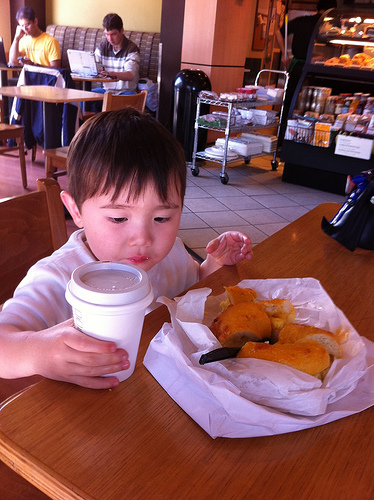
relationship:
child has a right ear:
[3, 98, 254, 390] [54, 188, 84, 228]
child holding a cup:
[3, 98, 254, 390] [65, 256, 159, 397]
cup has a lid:
[65, 256, 159, 397] [64, 262, 153, 314]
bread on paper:
[205, 278, 332, 379] [142, 278, 372, 443]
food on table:
[205, 278, 332, 379] [1, 196, 371, 499]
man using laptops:
[79, 17, 139, 98] [64, 45, 99, 77]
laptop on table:
[0, 39, 25, 71] [1, 64, 23, 87]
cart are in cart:
[189, 64, 285, 190] [189, 64, 285, 190]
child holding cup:
[3, 98, 254, 390] [65, 256, 159, 397]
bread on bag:
[205, 278, 332, 379] [142, 278, 372, 443]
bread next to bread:
[205, 278, 332, 379] [237, 335, 332, 388]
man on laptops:
[79, 17, 139, 98] [64, 45, 99, 77]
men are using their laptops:
[4, 11, 140, 96] [0, 35, 116, 82]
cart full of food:
[189, 64, 285, 190] [200, 80, 279, 130]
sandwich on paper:
[205, 278, 332, 379] [187, 267, 361, 397]